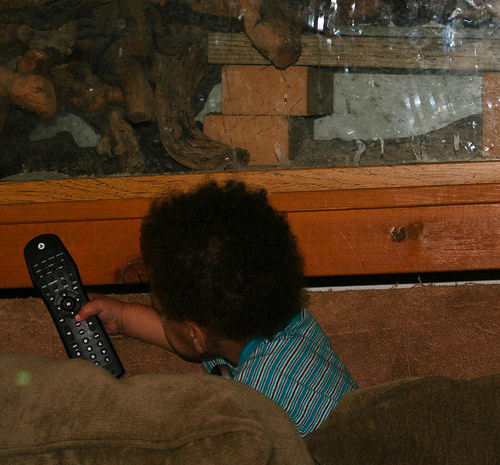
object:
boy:
[72, 179, 358, 441]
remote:
[22, 233, 125, 378]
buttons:
[63, 325, 75, 342]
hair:
[139, 176, 312, 343]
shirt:
[200, 309, 359, 440]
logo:
[37, 242, 47, 251]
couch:
[0, 352, 499, 465]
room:
[0, 0, 499, 465]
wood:
[206, 30, 499, 72]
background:
[0, 0, 499, 465]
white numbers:
[89, 353, 95, 360]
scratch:
[327, 222, 369, 272]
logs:
[0, 63, 59, 117]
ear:
[184, 319, 208, 355]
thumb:
[73, 299, 102, 323]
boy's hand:
[71, 291, 125, 333]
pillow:
[0, 353, 319, 465]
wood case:
[0, 201, 499, 290]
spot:
[13, 369, 35, 385]